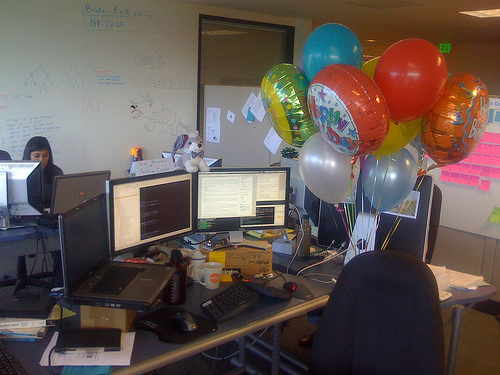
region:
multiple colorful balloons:
[264, 33, 491, 241]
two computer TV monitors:
[64, 162, 318, 262]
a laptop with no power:
[37, 193, 137, 296]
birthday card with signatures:
[223, 231, 293, 311]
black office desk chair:
[314, 237, 400, 373]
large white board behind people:
[30, 25, 190, 163]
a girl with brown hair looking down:
[17, 120, 76, 198]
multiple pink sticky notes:
[454, 144, 484, 192]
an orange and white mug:
[198, 255, 218, 299]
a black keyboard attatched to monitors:
[249, 269, 316, 298]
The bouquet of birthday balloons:
[255, 18, 493, 265]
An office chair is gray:
[304, 248, 451, 374]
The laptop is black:
[45, 190, 177, 312]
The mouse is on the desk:
[166, 306, 203, 338]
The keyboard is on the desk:
[198, 271, 294, 322]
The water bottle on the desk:
[160, 240, 191, 308]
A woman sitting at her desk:
[18, 131, 68, 221]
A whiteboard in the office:
[13, 42, 228, 184]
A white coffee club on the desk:
[191, 256, 230, 291]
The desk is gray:
[16, 241, 356, 372]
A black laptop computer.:
[55, 196, 175, 311]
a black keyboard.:
[201, 281, 291, 318]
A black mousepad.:
[137, 305, 217, 341]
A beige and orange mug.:
[194, 262, 222, 288]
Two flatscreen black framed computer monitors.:
[104, 167, 291, 257]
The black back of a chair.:
[306, 248, 448, 373]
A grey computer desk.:
[0, 226, 497, 373]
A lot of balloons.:
[254, 12, 494, 283]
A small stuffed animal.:
[171, 134, 212, 175]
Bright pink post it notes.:
[437, 130, 498, 192]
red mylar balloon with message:
[304, 60, 389, 162]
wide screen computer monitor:
[196, 164, 291, 235]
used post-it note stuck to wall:
[478, 177, 489, 192]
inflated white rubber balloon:
[296, 131, 358, 208]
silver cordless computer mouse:
[170, 308, 199, 333]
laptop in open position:
[55, 188, 175, 313]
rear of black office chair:
[313, 246, 449, 368]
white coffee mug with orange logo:
[196, 259, 222, 289]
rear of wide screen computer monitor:
[1, 158, 43, 218]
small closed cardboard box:
[201, 236, 271, 284]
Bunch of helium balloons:
[256, 25, 491, 219]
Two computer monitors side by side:
[106, 169, 283, 249]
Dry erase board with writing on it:
[2, 0, 192, 141]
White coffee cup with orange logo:
[194, 260, 223, 292]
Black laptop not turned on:
[44, 197, 136, 317]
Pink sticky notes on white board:
[463, 138, 498, 189]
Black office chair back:
[303, 249, 442, 368]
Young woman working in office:
[28, 129, 60, 201]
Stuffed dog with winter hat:
[166, 126, 215, 174]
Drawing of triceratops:
[123, 83, 194, 138]